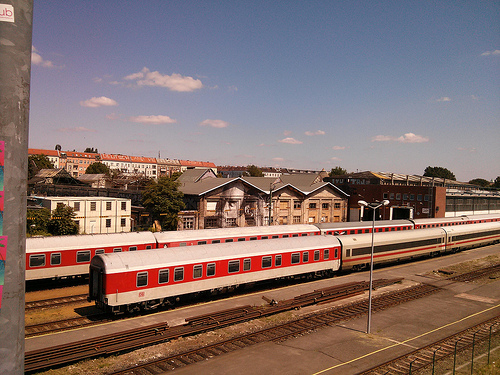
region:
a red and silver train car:
[89, 241, 339, 303]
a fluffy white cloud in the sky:
[131, 61, 201, 92]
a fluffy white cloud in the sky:
[381, 125, 427, 150]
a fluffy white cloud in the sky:
[126, 107, 191, 129]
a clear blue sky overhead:
[36, 8, 458, 96]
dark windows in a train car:
[31, 252, 66, 268]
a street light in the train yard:
[358, 200, 390, 336]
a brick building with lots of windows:
[374, 181, 442, 214]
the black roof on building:
[39, 172, 114, 195]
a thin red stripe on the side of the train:
[349, 254, 389, 259]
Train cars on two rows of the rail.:
[27, 212, 492, 319]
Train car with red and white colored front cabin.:
[87, 217, 492, 318]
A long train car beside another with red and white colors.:
[17, 213, 495, 305]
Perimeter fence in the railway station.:
[379, 309, 496, 373]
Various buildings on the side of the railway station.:
[27, 129, 497, 235]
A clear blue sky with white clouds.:
[39, 3, 491, 171]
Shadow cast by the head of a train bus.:
[74, 294, 121, 322]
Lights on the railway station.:
[354, 197, 391, 337]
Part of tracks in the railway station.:
[27, 295, 103, 335]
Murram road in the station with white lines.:
[268, 305, 493, 373]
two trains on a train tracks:
[26, 213, 498, 322]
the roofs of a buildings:
[206, 175, 333, 192]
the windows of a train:
[132, 244, 339, 292]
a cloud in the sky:
[120, 60, 210, 95]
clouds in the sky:
[265, 112, 442, 159]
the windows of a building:
[306, 200, 342, 212]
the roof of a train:
[127, 248, 191, 268]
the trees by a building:
[134, 176, 187, 216]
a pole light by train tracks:
[350, 185, 390, 340]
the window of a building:
[101, 201, 129, 233]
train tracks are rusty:
[208, 288, 415, 326]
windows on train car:
[93, 248, 349, 294]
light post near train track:
[356, 198, 389, 337]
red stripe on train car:
[102, 244, 343, 282]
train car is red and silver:
[88, 249, 357, 307]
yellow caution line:
[89, 311, 163, 323]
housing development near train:
[181, 156, 351, 226]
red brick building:
[365, 185, 443, 216]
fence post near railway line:
[406, 324, 498, 374]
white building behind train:
[44, 195, 134, 233]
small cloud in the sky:
[120, 65, 202, 95]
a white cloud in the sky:
[124, 68, 201, 93]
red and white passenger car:
[89, 231, 341, 319]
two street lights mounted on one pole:
[356, 197, 389, 327]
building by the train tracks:
[175, 174, 345, 228]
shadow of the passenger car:
[73, 306, 111, 321]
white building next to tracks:
[27, 197, 132, 230]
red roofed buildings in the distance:
[64, 148, 216, 169]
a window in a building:
[309, 202, 316, 210]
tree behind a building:
[424, 166, 456, 182]